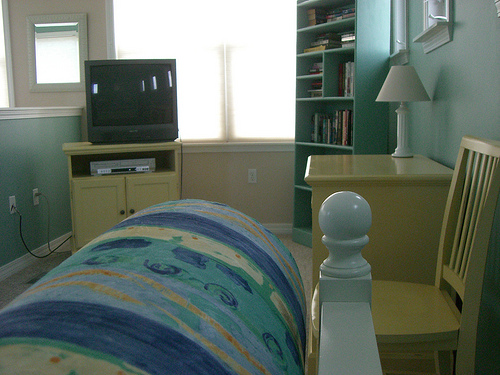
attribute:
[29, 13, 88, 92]
frame — white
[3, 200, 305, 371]
blanket — blue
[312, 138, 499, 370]
chair — yellow, beige, wooden, light wood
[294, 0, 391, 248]
bookcase — green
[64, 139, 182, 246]
stand — yellow, light wood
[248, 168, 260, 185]
electrical outlet — empty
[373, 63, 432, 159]
lamp — white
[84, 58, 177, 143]
television — black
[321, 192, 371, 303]
pole — white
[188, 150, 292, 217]
wall — pastel pink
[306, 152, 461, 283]
dresser — shiny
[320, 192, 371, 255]
knob — white, round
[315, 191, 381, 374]
bed post — white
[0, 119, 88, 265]
wall — green